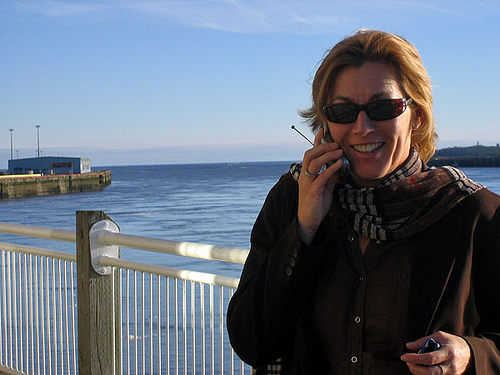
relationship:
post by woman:
[74, 209, 123, 374] [226, 28, 498, 373]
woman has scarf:
[226, 28, 498, 373] [286, 148, 485, 242]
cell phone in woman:
[290, 125, 351, 176] [226, 28, 498, 373]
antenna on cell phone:
[281, 111, 315, 151] [311, 115, 353, 177]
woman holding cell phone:
[226, 28, 498, 373] [291, 125, 358, 172]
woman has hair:
[226, 28, 498, 373] [296, 27, 443, 164]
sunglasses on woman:
[324, 97, 408, 122] [226, 28, 498, 373]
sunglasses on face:
[324, 97, 408, 122] [315, 74, 414, 172]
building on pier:
[7, 156, 90, 175] [17, 169, 79, 183]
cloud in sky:
[193, 7, 285, 34] [0, 0, 500, 167]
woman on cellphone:
[226, 28, 498, 373] [307, 104, 354, 187]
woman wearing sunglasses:
[226, 28, 498, 373] [275, 21, 442, 191]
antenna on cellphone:
[290, 125, 315, 145] [282, 104, 344, 181]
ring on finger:
[301, 166, 318, 182] [296, 145, 345, 185]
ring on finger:
[411, 316, 465, 358] [405, 355, 463, 373]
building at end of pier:
[5, 147, 97, 184] [0, 171, 113, 201]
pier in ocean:
[0, 171, 113, 201] [130, 182, 157, 212]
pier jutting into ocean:
[0, 171, 113, 201] [1, 165, 498, 372]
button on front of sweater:
[350, 274, 365, 281] [277, 171, 489, 373]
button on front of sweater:
[349, 310, 361, 323] [277, 171, 489, 373]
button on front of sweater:
[343, 353, 363, 362] [277, 171, 489, 373]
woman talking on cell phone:
[226, 28, 498, 373] [290, 125, 351, 176]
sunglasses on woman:
[322, 98, 414, 126] [226, 28, 498, 373]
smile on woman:
[343, 137, 388, 157] [226, 28, 498, 373]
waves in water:
[98, 159, 282, 206] [126, 154, 298, 185]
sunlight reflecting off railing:
[168, 237, 220, 290] [0, 222, 252, 292]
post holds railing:
[68, 201, 118, 364] [0, 222, 252, 292]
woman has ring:
[226, 28, 498, 373] [439, 362, 445, 373]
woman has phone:
[226, 28, 498, 373] [304, 99, 345, 180]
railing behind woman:
[86, 216, 228, 373] [226, 28, 498, 373]